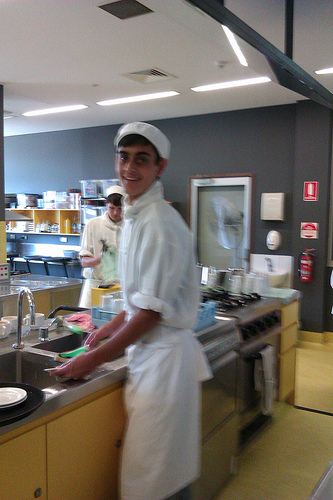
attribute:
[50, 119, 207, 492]
man — young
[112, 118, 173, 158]
hat — white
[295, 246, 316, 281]
fire extinguisher — red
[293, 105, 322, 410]
wall — small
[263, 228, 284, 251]
dispenser — soap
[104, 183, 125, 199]
hat — white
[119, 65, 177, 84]
air vent — white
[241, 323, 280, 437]
door — oven, closed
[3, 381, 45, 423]
tray — black